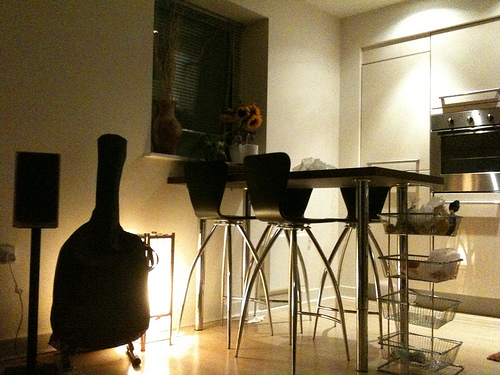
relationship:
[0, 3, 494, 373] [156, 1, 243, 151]
home has window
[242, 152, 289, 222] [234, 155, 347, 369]
back seat of bar stool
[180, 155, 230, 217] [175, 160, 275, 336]
back seat of bar stool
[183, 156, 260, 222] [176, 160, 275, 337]
seat of bar stool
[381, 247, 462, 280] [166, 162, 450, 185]
basket by table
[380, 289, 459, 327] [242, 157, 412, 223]
basket by table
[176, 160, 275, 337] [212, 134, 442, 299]
bar stool at table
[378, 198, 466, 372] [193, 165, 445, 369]
baskets on table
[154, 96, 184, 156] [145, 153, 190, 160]
vase on sill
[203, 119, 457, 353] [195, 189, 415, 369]
table has legs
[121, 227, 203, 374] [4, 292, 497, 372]
glow on floor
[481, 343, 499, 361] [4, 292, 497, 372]
rug on floor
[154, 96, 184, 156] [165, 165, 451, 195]
vase near table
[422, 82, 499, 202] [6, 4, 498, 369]
oven in kitchen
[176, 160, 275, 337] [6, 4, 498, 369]
bar stool in kitchen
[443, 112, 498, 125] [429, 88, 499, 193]
knobs on oven